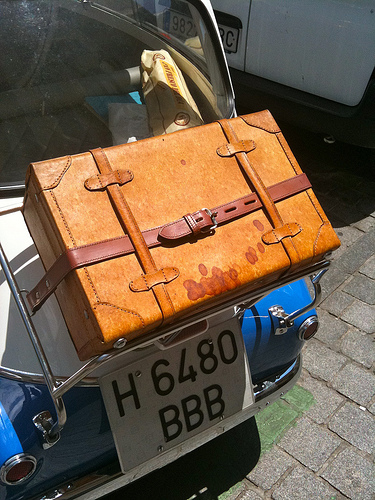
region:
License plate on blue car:
[85, 308, 254, 473]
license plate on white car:
[165, 6, 242, 51]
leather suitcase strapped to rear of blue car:
[32, 105, 339, 345]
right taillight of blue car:
[296, 314, 328, 345]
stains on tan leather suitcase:
[175, 215, 265, 295]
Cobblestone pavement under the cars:
[218, 210, 368, 488]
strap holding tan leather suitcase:
[30, 167, 320, 334]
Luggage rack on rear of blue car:
[0, 195, 346, 435]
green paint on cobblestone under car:
[111, 379, 307, 491]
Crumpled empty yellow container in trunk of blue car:
[124, 45, 201, 135]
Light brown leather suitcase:
[43, 137, 350, 259]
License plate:
[99, 353, 265, 421]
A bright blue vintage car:
[18, 105, 306, 393]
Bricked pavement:
[285, 375, 340, 482]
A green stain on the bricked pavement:
[237, 392, 320, 447]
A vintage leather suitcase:
[34, 111, 334, 262]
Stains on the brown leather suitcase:
[120, 266, 297, 317]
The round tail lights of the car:
[275, 305, 331, 346]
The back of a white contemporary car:
[225, 4, 345, 121]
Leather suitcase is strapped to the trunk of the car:
[12, 211, 343, 285]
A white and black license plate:
[82, 313, 275, 464]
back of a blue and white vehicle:
[2, 185, 322, 496]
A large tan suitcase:
[38, 96, 355, 361]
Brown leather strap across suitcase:
[30, 173, 333, 311]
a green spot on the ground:
[246, 376, 317, 451]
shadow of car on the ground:
[125, 404, 303, 498]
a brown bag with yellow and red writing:
[118, 32, 210, 152]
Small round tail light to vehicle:
[295, 314, 330, 364]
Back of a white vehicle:
[143, 1, 373, 115]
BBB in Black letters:
[149, 378, 249, 450]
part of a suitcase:
[175, 146, 213, 195]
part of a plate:
[183, 371, 223, 406]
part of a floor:
[271, 439, 312, 476]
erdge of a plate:
[149, 431, 193, 460]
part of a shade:
[223, 436, 256, 467]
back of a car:
[39, 420, 86, 471]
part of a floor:
[287, 402, 323, 443]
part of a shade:
[225, 460, 254, 478]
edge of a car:
[257, 378, 287, 409]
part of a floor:
[270, 429, 306, 465]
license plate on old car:
[96, 309, 255, 481]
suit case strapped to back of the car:
[20, 106, 340, 364]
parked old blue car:
[1, 8, 341, 498]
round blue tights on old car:
[0, 311, 322, 491]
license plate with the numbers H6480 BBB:
[97, 327, 271, 447]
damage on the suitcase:
[174, 218, 291, 307]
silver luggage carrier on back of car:
[1, 238, 334, 449]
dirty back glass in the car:
[2, 4, 176, 142]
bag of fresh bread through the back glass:
[135, 45, 204, 142]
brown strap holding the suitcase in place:
[15, 166, 323, 315]